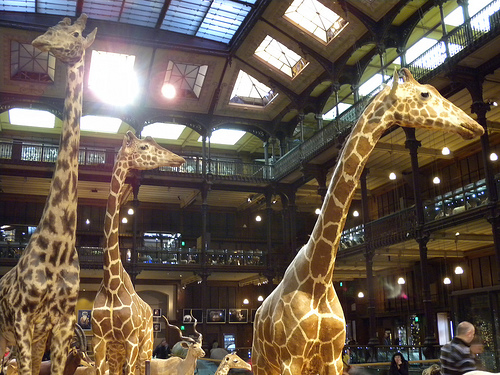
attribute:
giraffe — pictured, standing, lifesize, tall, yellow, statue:
[265, 11, 470, 375]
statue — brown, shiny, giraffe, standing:
[12, 13, 75, 375]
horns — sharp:
[54, 16, 94, 30]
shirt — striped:
[429, 335, 474, 372]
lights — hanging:
[429, 240, 483, 299]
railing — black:
[330, 195, 499, 263]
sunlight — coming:
[95, 47, 137, 111]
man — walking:
[442, 307, 481, 374]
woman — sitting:
[379, 350, 417, 375]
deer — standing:
[146, 336, 211, 372]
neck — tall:
[307, 106, 395, 310]